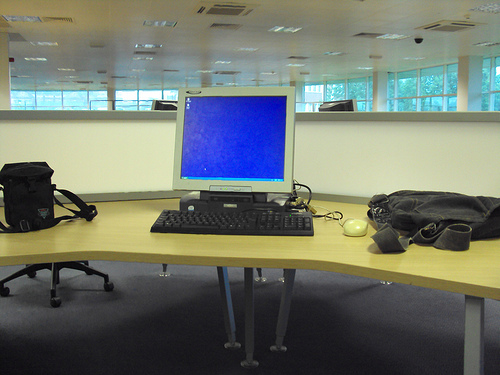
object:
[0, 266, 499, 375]
floor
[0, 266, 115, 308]
wheels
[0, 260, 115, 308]
chair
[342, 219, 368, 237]
mouse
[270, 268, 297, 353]
leg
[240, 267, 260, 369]
leg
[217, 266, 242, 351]
leg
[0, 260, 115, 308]
trees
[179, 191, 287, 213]
cpu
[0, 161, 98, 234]
bag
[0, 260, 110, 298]
chair legs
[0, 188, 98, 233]
strap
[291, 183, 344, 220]
black cord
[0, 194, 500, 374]
desk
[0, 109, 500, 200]
dividing wall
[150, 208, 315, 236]
computer keyboard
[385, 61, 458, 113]
windows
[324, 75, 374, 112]
windows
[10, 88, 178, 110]
windows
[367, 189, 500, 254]
backpack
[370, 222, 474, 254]
straps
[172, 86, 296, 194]
monitor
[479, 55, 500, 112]
windows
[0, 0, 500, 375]
office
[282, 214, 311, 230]
keypad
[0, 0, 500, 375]
room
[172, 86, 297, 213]
computer